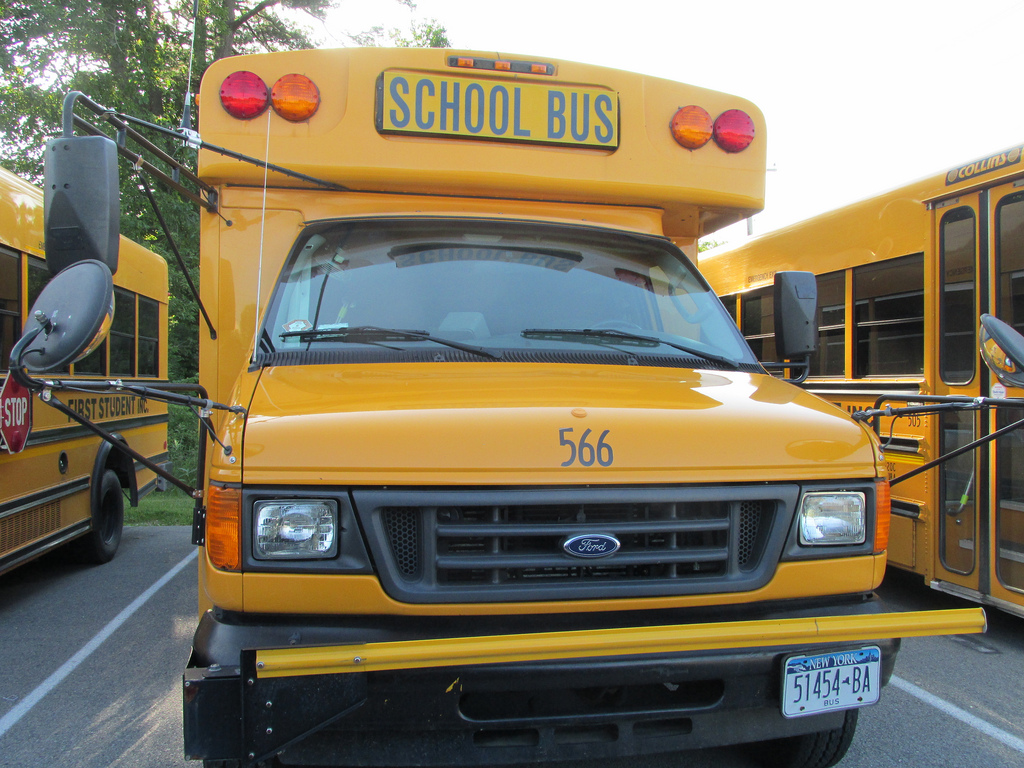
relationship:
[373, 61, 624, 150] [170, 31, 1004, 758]
sign on bus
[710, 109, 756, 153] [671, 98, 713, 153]
light next to light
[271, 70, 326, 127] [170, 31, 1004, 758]
light on bus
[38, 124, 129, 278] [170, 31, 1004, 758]
mirror on bus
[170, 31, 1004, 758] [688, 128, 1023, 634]
bus parked next to bus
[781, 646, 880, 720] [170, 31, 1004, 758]
license plate on front of bus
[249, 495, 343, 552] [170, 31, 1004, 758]
headlight on bus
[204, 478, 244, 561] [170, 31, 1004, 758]
light on bus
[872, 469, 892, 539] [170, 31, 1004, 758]
light on bus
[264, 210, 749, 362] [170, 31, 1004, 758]
windshield on bus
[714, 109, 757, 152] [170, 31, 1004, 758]
light on bus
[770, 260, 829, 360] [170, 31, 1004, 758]
mirror on bus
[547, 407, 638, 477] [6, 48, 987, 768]
number on bus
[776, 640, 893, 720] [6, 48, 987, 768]
license plate on bus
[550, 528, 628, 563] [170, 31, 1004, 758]
ford symbol on bus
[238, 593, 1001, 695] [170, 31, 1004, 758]
crossing arm on bus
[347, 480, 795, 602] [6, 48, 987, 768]
grill on bus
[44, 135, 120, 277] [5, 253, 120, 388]
mirror with mirror